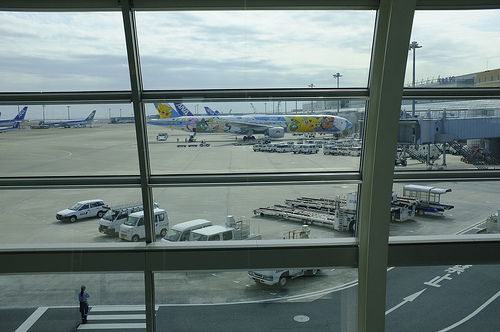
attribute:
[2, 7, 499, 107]
sky — cloudy